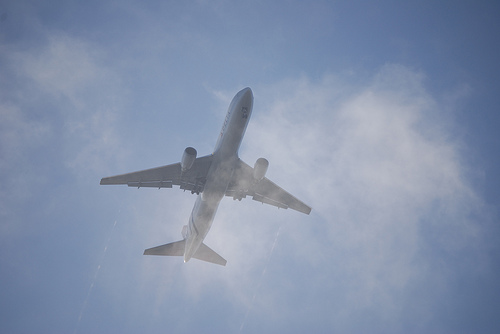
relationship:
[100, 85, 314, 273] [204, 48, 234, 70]
airplane in sky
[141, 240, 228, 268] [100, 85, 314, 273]
tail of airplane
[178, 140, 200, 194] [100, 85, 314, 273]
engine on airplane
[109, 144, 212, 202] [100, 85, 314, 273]
wing of airplane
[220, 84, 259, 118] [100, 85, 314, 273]
nose of airplane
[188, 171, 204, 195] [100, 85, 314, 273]
landing gear of airplane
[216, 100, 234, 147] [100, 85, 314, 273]
writing on airplane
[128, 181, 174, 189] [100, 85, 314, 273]
landing flap of a airplane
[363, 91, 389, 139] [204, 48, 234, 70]
cloud in sky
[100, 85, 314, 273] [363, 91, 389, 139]
airplane in cloud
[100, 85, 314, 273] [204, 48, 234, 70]
airplane flying in sky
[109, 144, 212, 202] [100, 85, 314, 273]
wing on airplane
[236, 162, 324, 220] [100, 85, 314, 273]
wing on airplane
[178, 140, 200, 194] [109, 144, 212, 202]
engine on wing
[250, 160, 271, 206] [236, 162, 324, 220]
engine of wing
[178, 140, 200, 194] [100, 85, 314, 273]
engine of a airplane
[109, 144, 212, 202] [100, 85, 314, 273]
wing of a airplane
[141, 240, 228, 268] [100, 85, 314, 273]
tail of a airplane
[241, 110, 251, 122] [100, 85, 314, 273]
wheel of airplane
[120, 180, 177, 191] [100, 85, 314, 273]
landing flap of airplane